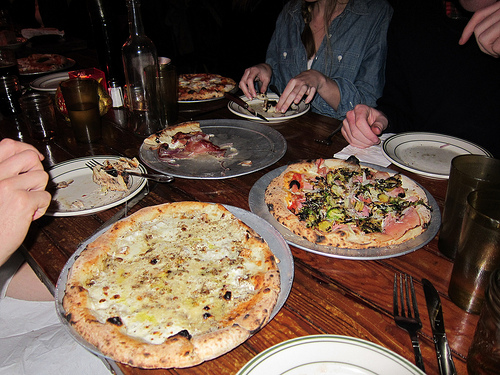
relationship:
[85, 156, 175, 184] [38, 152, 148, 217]
fork laying on plate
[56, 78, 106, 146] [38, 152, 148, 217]
cup near plate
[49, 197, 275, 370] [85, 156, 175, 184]
pizza near fork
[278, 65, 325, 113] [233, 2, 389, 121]
hand of woman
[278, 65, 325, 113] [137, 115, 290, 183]
hand near pan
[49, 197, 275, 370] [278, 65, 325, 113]
pizza near hand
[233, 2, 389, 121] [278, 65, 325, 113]
woman with a hand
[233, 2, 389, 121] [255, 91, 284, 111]
woman eating pizza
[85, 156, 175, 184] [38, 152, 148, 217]
fork on plate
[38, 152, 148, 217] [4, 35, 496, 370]
plate on table